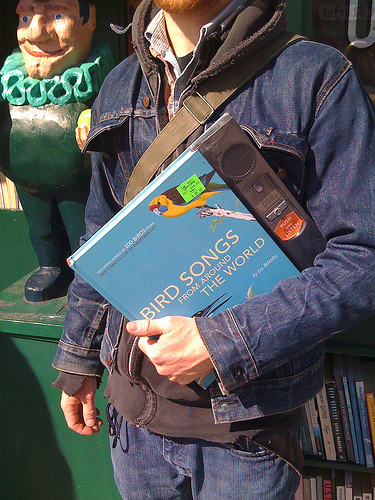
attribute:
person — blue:
[56, 2, 374, 499]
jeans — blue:
[105, 403, 299, 499]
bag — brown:
[122, 34, 306, 210]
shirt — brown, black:
[48, 1, 310, 446]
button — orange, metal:
[140, 97, 150, 111]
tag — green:
[177, 173, 207, 205]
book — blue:
[65, 113, 326, 342]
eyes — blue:
[57, 13, 63, 20]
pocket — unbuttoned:
[82, 114, 140, 204]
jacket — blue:
[57, 2, 374, 423]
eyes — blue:
[20, 12, 29, 22]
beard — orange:
[152, 0, 221, 14]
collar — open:
[146, 18, 219, 122]